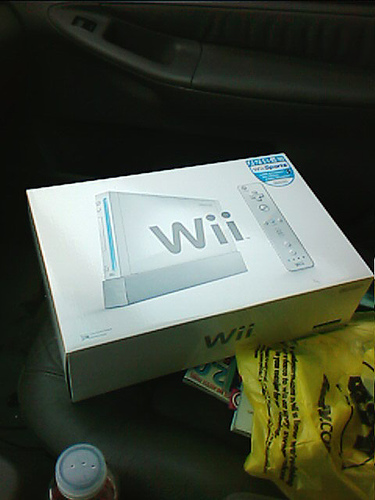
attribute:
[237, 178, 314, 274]
remote — depiction of remote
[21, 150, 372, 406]
box — white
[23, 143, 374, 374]
wii — white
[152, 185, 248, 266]
text — gray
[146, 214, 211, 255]
letter — w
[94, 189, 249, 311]
console — depiction 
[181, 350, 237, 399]
magazine — beneath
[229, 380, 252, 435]
magazine — beneath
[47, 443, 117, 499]
bottle — plastic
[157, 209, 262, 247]
writing — gray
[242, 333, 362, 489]
bag — yellow